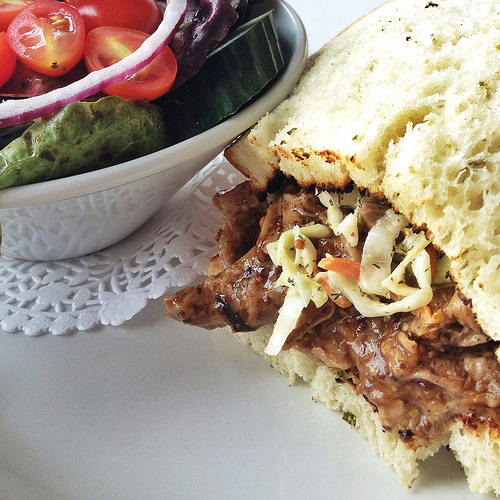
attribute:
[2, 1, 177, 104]
tomatoes — cut in half, red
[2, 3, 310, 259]
bowl — white, made of glass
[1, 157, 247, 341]
doily — white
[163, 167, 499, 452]
meat — brown, juicy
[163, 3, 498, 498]
sandwich — thick, toasted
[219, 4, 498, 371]
bread — white, toasted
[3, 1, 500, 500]
surface — white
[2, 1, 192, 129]
onion — red, sliced, purple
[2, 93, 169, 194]
lettuce — green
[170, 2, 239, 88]
cabbage — red, purple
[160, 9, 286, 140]
cucumber — thick